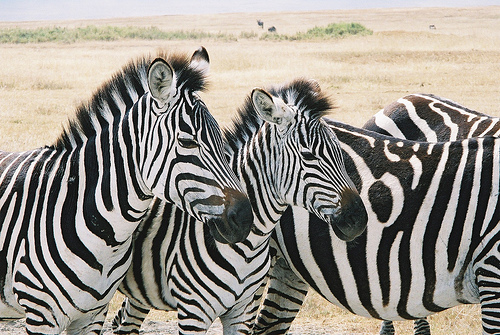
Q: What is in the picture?
A: Zebras.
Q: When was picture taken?
A: Daytime.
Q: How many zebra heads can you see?
A: Two.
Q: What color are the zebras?
A: Black and white.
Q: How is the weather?
A: Nice.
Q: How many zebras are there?
A: Four.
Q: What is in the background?
A: Flatland.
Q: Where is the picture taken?
A: Africa.